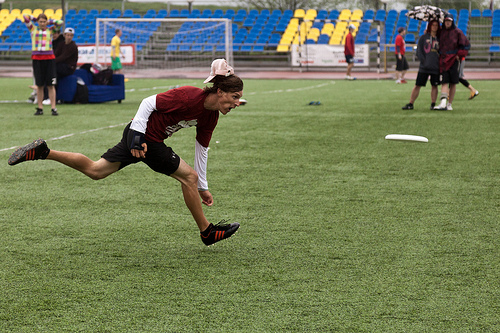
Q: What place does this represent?
A: It represents the field.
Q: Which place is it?
A: It is a field.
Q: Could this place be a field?
A: Yes, it is a field.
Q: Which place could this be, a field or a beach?
A: It is a field.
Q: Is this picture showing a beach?
A: No, the picture is showing a field.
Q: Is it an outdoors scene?
A: Yes, it is outdoors.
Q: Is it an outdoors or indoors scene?
A: It is outdoors.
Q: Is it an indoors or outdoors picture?
A: It is outdoors.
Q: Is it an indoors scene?
A: No, it is outdoors.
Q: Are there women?
A: Yes, there is a woman.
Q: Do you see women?
A: Yes, there is a woman.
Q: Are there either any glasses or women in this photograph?
A: Yes, there is a woman.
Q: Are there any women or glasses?
A: Yes, there is a woman.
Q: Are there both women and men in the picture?
A: Yes, there are both a woman and a man.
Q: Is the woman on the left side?
A: Yes, the woman is on the left of the image.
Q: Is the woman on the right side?
A: No, the woman is on the left of the image.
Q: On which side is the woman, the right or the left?
A: The woman is on the left of the image.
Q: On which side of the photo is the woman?
A: The woman is on the left of the image.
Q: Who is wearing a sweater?
A: The woman is wearing a sweater.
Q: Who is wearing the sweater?
A: The woman is wearing a sweater.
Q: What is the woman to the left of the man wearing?
A: The woman is wearing a sweater.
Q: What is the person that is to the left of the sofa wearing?
A: The woman is wearing a sweater.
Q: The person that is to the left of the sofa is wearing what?
A: The woman is wearing a sweater.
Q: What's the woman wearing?
A: The woman is wearing a sweater.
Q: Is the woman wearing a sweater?
A: Yes, the woman is wearing a sweater.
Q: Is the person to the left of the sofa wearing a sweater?
A: Yes, the woman is wearing a sweater.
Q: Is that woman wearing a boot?
A: No, the woman is wearing a sweater.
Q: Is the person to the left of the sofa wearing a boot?
A: No, the woman is wearing a sweater.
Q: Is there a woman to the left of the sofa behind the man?
A: Yes, there is a woman to the left of the sofa.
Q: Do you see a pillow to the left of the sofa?
A: No, there is a woman to the left of the sofa.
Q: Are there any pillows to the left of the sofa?
A: No, there is a woman to the left of the sofa.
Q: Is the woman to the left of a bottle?
A: No, the woman is to the left of the sofa.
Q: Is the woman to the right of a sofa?
A: No, the woman is to the left of a sofa.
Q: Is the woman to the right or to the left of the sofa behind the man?
A: The woman is to the left of the sofa.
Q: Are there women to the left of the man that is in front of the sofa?
A: Yes, there is a woman to the left of the man.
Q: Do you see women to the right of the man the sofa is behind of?
A: No, the woman is to the left of the man.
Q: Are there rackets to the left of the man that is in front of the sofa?
A: No, there is a woman to the left of the man.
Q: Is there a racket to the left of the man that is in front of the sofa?
A: No, there is a woman to the left of the man.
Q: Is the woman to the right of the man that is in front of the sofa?
A: No, the woman is to the left of the man.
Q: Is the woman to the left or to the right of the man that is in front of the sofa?
A: The woman is to the left of the man.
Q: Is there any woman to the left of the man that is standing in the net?
A: Yes, there is a woman to the left of the man.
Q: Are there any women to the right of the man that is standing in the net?
A: No, the woman is to the left of the man.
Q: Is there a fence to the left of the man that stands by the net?
A: No, there is a woman to the left of the man.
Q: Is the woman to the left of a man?
A: Yes, the woman is to the left of a man.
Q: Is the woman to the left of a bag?
A: No, the woman is to the left of a man.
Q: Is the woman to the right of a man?
A: No, the woman is to the left of a man.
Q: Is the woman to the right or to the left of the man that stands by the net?
A: The woman is to the left of the man.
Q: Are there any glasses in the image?
A: No, there are no glasses.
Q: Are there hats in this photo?
A: Yes, there is a hat.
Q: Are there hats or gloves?
A: Yes, there is a hat.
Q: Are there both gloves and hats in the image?
A: Yes, there are both a hat and gloves.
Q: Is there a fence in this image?
A: No, there are no fences.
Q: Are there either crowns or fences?
A: No, there are no fences or crowns.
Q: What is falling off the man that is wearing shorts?
A: The hat is falling off the man.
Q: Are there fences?
A: No, there are no fences.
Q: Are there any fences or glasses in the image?
A: No, there are no fences or glasses.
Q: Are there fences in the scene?
A: No, there are no fences.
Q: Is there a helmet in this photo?
A: No, there are no helmets.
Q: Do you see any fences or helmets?
A: No, there are no helmets or fences.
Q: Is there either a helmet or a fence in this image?
A: No, there are no helmets or fences.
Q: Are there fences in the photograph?
A: No, there are no fences.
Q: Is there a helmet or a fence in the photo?
A: No, there are no fences or helmets.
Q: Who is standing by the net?
A: The man is standing by the net.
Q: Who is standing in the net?
A: The man is standing in the net.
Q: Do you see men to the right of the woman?
A: Yes, there is a man to the right of the woman.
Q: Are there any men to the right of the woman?
A: Yes, there is a man to the right of the woman.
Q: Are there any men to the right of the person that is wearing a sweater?
A: Yes, there is a man to the right of the woman.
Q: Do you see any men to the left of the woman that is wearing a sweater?
A: No, the man is to the right of the woman.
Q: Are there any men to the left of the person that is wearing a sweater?
A: No, the man is to the right of the woman.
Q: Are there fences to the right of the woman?
A: No, there is a man to the right of the woman.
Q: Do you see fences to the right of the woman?
A: No, there is a man to the right of the woman.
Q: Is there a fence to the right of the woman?
A: No, there is a man to the right of the woman.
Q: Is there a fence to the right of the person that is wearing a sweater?
A: No, there is a man to the right of the woman.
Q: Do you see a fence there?
A: No, there are no fences.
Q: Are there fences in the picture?
A: No, there are no fences.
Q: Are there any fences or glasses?
A: No, there are no fences or glasses.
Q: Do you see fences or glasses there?
A: No, there are no fences or glasses.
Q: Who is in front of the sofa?
A: The man is in front of the sofa.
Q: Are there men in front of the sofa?
A: Yes, there is a man in front of the sofa.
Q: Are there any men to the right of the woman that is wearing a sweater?
A: Yes, there is a man to the right of the woman.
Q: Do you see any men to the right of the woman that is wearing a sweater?
A: Yes, there is a man to the right of the woman.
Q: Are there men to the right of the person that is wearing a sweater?
A: Yes, there is a man to the right of the woman.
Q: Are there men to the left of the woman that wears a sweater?
A: No, the man is to the right of the woman.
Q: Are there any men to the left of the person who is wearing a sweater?
A: No, the man is to the right of the woman.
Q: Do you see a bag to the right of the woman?
A: No, there is a man to the right of the woman.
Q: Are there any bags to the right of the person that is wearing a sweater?
A: No, there is a man to the right of the woman.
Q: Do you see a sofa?
A: Yes, there is a sofa.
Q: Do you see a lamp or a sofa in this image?
A: Yes, there is a sofa.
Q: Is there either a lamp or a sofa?
A: Yes, there is a sofa.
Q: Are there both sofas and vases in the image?
A: No, there is a sofa but no vases.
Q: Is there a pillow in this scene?
A: No, there are no pillows.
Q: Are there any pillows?
A: No, there are no pillows.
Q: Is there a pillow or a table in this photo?
A: No, there are no pillows or tables.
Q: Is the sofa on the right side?
A: No, the sofa is on the left of the image.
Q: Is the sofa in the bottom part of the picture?
A: No, the sofa is in the top of the image.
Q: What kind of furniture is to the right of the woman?
A: The piece of furniture is a sofa.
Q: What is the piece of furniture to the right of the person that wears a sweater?
A: The piece of furniture is a sofa.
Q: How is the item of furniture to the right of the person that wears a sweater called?
A: The piece of furniture is a sofa.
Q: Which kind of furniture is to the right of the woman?
A: The piece of furniture is a sofa.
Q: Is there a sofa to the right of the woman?
A: Yes, there is a sofa to the right of the woman.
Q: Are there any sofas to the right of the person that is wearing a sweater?
A: Yes, there is a sofa to the right of the woman.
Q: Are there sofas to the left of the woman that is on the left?
A: No, the sofa is to the right of the woman.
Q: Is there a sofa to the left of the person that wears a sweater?
A: No, the sofa is to the right of the woman.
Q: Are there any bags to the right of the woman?
A: No, there is a sofa to the right of the woman.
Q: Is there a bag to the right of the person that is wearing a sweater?
A: No, there is a sofa to the right of the woman.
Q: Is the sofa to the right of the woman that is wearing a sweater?
A: Yes, the sofa is to the right of the woman.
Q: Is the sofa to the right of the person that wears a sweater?
A: Yes, the sofa is to the right of the woman.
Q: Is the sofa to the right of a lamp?
A: No, the sofa is to the right of the woman.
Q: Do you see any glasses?
A: No, there are no glasses.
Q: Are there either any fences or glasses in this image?
A: No, there are no glasses or fences.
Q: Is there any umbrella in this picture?
A: Yes, there is an umbrella.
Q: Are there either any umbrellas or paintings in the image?
A: Yes, there is an umbrella.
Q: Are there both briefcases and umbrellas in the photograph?
A: No, there is an umbrella but no briefcases.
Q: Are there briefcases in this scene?
A: No, there are no briefcases.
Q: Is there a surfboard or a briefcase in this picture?
A: No, there are no briefcases or surfboards.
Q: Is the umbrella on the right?
A: Yes, the umbrella is on the right of the image.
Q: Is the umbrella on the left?
A: No, the umbrella is on the right of the image.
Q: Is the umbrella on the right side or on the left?
A: The umbrella is on the right of the image.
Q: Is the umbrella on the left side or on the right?
A: The umbrella is on the right of the image.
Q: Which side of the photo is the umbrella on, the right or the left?
A: The umbrella is on the right of the image.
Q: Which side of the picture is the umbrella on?
A: The umbrella is on the right of the image.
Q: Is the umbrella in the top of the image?
A: Yes, the umbrella is in the top of the image.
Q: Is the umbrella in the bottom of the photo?
A: No, the umbrella is in the top of the image.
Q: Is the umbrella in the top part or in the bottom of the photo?
A: The umbrella is in the top of the image.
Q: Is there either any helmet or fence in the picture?
A: No, there are no fences or helmets.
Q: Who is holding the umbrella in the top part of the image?
A: The man is holding the umbrella.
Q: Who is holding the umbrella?
A: The man is holding the umbrella.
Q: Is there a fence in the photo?
A: No, there are no fences.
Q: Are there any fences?
A: No, there are no fences.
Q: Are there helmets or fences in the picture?
A: No, there are no fences or helmets.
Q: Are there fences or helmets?
A: No, there are no fences or helmets.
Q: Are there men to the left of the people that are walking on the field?
A: Yes, there is a man to the left of the people.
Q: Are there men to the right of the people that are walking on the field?
A: No, the man is to the left of the people.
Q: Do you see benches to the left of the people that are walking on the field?
A: No, there is a man to the left of the people.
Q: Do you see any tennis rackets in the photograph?
A: No, there are no tennis rackets.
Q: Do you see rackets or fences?
A: No, there are no rackets or fences.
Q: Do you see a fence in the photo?
A: No, there are no fences.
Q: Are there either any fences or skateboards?
A: No, there are no fences or skateboards.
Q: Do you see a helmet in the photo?
A: No, there are no helmets.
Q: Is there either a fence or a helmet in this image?
A: No, there are no helmets or fences.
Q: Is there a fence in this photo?
A: No, there are no fences.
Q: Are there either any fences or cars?
A: No, there are no fences or cars.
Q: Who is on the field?
A: The people are on the field.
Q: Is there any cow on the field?
A: No, there are people on the field.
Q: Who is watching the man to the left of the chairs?
A: The people are watching the man.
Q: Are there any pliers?
A: No, there are no pliers.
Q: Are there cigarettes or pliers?
A: No, there are no pliers or cigarettes.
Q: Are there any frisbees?
A: Yes, there is a frisbee.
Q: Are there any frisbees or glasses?
A: Yes, there is a frisbee.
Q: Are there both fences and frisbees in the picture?
A: No, there is a frisbee but no fences.